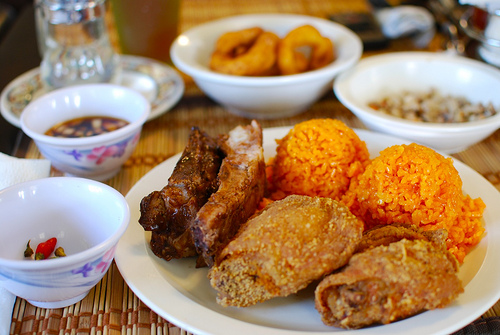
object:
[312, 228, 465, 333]
egg roll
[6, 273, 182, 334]
bamboo placemat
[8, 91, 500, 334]
placemat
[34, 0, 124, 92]
grinder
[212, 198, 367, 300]
egg roll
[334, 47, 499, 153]
bowl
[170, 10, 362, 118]
bowl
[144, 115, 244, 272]
meat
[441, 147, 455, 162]
ground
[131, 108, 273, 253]
ribs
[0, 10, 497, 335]
table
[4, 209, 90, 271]
peppers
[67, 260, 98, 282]
flower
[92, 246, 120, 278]
flower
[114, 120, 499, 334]
plate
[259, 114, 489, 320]
rice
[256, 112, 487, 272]
rice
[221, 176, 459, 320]
chicken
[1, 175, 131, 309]
bowl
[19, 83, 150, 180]
bowl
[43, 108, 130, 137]
dark sauce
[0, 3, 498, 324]
food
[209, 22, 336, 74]
onion rings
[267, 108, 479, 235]
stacks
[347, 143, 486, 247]
rice scoop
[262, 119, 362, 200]
rice scoop